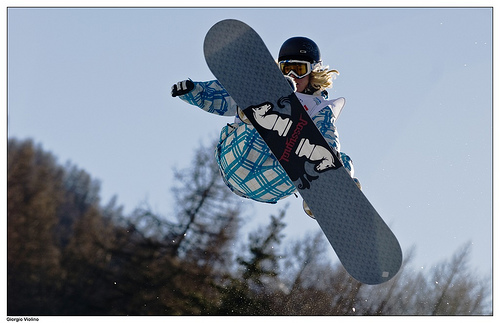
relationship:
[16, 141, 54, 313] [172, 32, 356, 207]
evergreen tree behind snowboarder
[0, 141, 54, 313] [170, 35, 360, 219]
evergreen tree behind snow boarder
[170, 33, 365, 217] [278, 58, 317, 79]
snow boarder wearing goggles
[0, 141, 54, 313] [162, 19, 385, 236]
evergreen tree behind snow boarder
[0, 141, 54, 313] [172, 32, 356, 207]
evergreen tree behind snowboarder